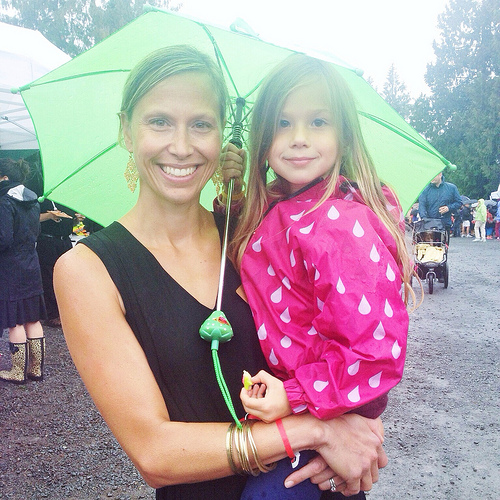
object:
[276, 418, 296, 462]
band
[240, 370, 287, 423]
hand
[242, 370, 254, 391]
food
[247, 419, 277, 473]
bangles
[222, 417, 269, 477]
group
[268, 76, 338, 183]
girl's face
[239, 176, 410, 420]
coat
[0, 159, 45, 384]
woman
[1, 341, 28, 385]
boots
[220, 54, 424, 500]
child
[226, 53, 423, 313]
hair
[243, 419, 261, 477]
bangles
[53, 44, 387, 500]
girl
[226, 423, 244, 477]
bangles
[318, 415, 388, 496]
hand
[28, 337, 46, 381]
boots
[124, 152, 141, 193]
gold earrings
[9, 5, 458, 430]
umbrella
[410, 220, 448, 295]
baby carriage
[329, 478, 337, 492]
ring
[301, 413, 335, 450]
wrist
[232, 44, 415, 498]
girl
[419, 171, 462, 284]
man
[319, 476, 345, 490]
finger